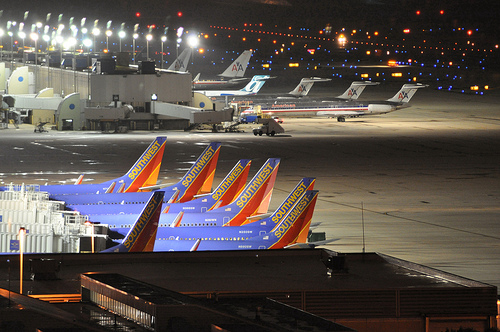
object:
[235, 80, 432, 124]
airplane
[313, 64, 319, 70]
lights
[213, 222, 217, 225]
windows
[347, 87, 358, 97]
logo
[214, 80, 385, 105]
plane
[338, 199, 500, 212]
line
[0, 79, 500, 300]
roadway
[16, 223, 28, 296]
pole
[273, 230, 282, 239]
letter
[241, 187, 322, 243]
tail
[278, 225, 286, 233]
letter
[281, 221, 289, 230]
letter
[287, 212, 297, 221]
letter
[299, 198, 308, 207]
letter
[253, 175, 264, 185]
letter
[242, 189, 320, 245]
plane tail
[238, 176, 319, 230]
plane tail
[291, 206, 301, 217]
letter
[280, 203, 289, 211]
letter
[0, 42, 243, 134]
gate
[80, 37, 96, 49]
lights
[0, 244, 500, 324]
roof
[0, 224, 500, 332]
building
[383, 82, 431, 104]
tail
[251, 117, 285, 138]
plane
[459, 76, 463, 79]
lights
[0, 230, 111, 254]
gates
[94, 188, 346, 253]
airplane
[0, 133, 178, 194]
airplane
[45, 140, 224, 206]
airplane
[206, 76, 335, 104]
airplane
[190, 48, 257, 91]
airplane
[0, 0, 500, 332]
airport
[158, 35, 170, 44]
lights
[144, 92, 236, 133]
jetbridge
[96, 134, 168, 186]
tail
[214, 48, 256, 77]
tail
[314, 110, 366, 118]
wing